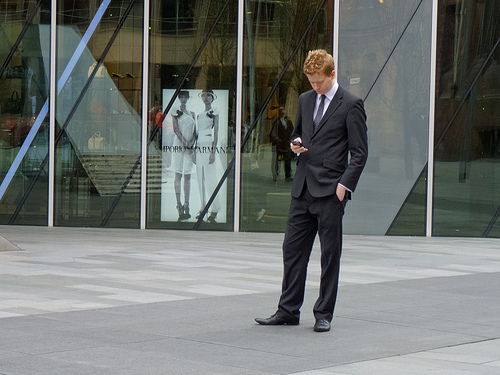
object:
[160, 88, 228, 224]
advertisement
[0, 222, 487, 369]
sidewalk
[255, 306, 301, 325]
shoes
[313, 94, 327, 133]
tie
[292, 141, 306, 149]
cell phone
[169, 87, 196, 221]
woman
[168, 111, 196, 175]
dress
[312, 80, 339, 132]
white shirt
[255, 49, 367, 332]
man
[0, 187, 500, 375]
street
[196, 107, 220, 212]
suit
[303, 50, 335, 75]
short hair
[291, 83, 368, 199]
jacket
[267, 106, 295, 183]
person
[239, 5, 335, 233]
window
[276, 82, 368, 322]
suit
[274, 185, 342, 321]
pants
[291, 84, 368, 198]
suit jacket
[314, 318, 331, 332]
dress shoes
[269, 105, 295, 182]
reflection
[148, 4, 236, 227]
window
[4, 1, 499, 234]
retail store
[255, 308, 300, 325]
man's feet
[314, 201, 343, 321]
man's legs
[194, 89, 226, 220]
woman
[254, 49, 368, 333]
boy